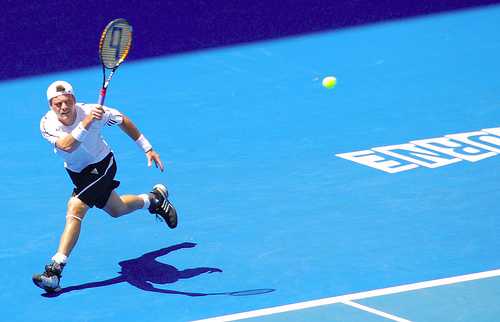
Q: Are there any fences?
A: No, there are no fences.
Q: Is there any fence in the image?
A: No, there are no fences.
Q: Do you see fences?
A: No, there are no fences.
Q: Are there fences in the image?
A: No, there are no fences.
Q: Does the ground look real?
A: Yes, the ground is real.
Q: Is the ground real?
A: Yes, the ground is real.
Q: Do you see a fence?
A: No, there are no fences.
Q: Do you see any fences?
A: No, there are no fences.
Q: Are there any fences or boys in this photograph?
A: No, there are no fences or boys.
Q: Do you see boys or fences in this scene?
A: No, there are no fences or boys.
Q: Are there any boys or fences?
A: No, there are no fences or boys.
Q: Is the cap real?
A: Yes, the cap is real.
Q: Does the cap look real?
A: Yes, the cap is real.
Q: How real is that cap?
A: The cap is real.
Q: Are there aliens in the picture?
A: No, there are no aliens.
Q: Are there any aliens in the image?
A: No, there are no aliens.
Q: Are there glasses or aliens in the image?
A: No, there are no aliens or glasses.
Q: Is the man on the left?
A: Yes, the man is on the left of the image.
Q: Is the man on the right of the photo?
A: No, the man is on the left of the image.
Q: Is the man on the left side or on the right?
A: The man is on the left of the image.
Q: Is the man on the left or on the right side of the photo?
A: The man is on the left of the image.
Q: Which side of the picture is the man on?
A: The man is on the left of the image.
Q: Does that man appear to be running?
A: Yes, the man is running.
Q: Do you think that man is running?
A: Yes, the man is running.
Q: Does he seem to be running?
A: Yes, the man is running.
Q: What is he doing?
A: The man is running.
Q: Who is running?
A: The man is running.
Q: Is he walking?
A: No, the man is running.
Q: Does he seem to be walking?
A: No, the man is running.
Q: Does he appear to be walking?
A: No, the man is running.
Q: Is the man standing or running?
A: The man is running.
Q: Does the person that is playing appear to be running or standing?
A: The man is running.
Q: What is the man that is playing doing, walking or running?
A: The man is running.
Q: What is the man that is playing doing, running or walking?
A: The man is running.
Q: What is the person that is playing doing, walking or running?
A: The man is running.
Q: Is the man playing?
A: Yes, the man is playing.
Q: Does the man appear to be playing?
A: Yes, the man is playing.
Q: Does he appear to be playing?
A: Yes, the man is playing.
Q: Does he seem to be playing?
A: Yes, the man is playing.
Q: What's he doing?
A: The man is playing.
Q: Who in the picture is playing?
A: The man is playing.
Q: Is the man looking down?
A: No, the man is playing.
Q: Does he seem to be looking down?
A: No, the man is playing.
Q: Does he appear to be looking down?
A: No, the man is playing.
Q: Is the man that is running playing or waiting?
A: The man is playing.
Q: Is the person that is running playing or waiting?
A: The man is playing.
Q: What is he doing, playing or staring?
A: The man is playing.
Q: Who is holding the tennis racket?
A: The man is holding the tennis racket.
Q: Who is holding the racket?
A: The man is holding the tennis racket.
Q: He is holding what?
A: The man is holding the tennis racket.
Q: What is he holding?
A: The man is holding the tennis racket.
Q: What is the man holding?
A: The man is holding the tennis racket.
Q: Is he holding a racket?
A: Yes, the man is holding a racket.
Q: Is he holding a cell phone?
A: No, the man is holding a racket.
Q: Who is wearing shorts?
A: The man is wearing shorts.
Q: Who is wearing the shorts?
A: The man is wearing shorts.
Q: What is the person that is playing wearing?
A: The man is wearing shorts.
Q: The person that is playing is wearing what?
A: The man is wearing shorts.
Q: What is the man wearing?
A: The man is wearing shorts.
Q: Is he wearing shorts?
A: Yes, the man is wearing shorts.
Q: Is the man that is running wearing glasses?
A: No, the man is wearing shorts.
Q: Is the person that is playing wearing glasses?
A: No, the man is wearing shorts.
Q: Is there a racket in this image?
A: Yes, there is a racket.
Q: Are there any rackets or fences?
A: Yes, there is a racket.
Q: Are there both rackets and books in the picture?
A: No, there is a racket but no books.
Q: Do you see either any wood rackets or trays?
A: Yes, there is a wood racket.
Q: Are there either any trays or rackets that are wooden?
A: Yes, the racket is wooden.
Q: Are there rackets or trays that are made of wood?
A: Yes, the racket is made of wood.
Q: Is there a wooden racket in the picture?
A: Yes, there is a wood racket.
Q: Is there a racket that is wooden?
A: Yes, there is a racket that is wooden.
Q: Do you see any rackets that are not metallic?
A: Yes, there is a wooden racket.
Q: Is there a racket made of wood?
A: Yes, there is a racket that is made of wood.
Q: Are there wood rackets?
A: Yes, there is a racket that is made of wood.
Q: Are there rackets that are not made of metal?
A: Yes, there is a racket that is made of wood.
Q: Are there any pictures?
A: No, there are no pictures.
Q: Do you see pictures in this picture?
A: No, there are no pictures.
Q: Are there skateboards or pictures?
A: No, there are no pictures or skateboards.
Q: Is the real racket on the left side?
A: Yes, the racket is on the left of the image.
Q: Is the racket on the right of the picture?
A: No, the racket is on the left of the image.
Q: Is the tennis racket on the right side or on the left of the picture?
A: The tennis racket is on the left of the image.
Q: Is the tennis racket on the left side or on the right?
A: The tennis racket is on the left of the image.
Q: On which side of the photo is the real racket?
A: The tennis racket is on the left of the image.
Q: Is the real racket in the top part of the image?
A: Yes, the racket is in the top of the image.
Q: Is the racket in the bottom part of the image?
A: No, the racket is in the top of the image.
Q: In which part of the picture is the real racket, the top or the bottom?
A: The tennis racket is in the top of the image.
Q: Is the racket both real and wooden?
A: Yes, the racket is real and wooden.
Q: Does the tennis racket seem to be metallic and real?
A: No, the tennis racket is real but wooden.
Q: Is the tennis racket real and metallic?
A: No, the tennis racket is real but wooden.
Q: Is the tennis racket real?
A: Yes, the tennis racket is real.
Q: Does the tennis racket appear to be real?
A: Yes, the tennis racket is real.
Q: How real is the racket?
A: The racket is real.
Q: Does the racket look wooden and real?
A: Yes, the racket is wooden and real.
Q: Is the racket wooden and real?
A: Yes, the racket is wooden and real.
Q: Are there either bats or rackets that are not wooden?
A: No, there is a racket but it is wooden.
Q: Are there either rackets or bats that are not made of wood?
A: No, there is a racket but it is made of wood.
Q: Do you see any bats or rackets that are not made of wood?
A: No, there is a racket but it is made of wood.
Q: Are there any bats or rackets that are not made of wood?
A: No, there is a racket but it is made of wood.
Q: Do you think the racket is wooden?
A: Yes, the racket is wooden.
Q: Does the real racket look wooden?
A: Yes, the tennis racket is wooden.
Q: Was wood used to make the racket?
A: Yes, the racket is made of wood.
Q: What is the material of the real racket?
A: The tennis racket is made of wood.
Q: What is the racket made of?
A: The tennis racket is made of wood.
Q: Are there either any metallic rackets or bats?
A: No, there is a racket but it is wooden.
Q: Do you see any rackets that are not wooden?
A: No, there is a racket but it is wooden.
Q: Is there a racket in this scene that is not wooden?
A: No, there is a racket but it is wooden.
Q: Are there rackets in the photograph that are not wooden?
A: No, there is a racket but it is wooden.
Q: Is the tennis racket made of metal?
A: No, the tennis racket is made of wood.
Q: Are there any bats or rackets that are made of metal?
A: No, there is a racket but it is made of wood.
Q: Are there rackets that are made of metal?
A: No, there is a racket but it is made of wood.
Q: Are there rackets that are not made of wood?
A: No, there is a racket but it is made of wood.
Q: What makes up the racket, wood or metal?
A: The racket is made of wood.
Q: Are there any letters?
A: Yes, there are letters.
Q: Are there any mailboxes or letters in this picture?
A: Yes, there are letters.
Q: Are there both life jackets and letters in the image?
A: No, there are letters but no life jackets.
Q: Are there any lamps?
A: No, there are no lamps.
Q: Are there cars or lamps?
A: No, there are no lamps or cars.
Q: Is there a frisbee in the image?
A: No, there are no frisbees.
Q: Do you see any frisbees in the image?
A: No, there are no frisbees.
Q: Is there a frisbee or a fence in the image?
A: No, there are no frisbees or fences.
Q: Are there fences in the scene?
A: No, there are no fences.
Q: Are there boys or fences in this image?
A: No, there are no fences or boys.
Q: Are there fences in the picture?
A: No, there are no fences.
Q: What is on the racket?
A: The logo is on the racket.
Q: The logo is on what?
A: The logo is on the tennis racket.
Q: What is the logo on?
A: The logo is on the tennis racket.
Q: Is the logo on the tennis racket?
A: Yes, the logo is on the tennis racket.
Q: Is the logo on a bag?
A: No, the logo is on the tennis racket.